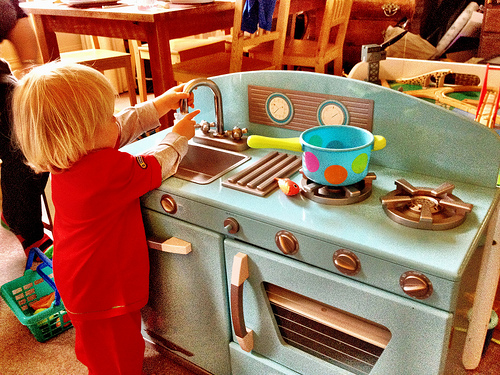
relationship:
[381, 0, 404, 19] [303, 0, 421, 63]
handles on bureau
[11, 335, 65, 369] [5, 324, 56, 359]
carpet on floor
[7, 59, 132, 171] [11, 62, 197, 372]
head on child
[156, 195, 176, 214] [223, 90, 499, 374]
knob on toy stove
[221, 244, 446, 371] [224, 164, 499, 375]
oven on stove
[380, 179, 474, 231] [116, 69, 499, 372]
burner on toy stove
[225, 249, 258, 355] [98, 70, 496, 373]
handle on stove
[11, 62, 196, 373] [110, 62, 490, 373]
boy playing with sink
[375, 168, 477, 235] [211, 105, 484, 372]
burner on stove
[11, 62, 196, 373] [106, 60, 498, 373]
boy playing at kitchen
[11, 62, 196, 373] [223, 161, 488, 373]
boy with oven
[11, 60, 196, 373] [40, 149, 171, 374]
boy wearing red clothes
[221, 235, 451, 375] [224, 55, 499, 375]
door on stove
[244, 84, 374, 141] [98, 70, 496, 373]
decoration on stove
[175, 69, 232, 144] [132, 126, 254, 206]
faucet on sink